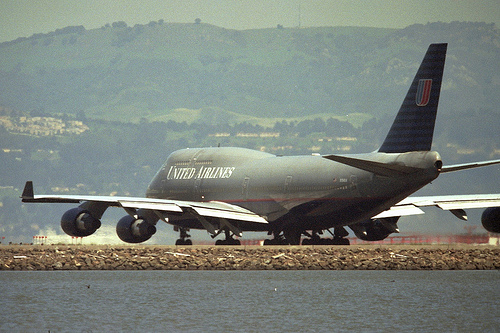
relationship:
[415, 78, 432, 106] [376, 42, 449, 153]
logo on stabilizer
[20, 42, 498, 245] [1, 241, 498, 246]
747 on runway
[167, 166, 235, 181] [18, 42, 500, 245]
sticker written on side of airplane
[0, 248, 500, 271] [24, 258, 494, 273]
rock overlooking rocks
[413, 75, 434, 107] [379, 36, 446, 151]
logo on plane tail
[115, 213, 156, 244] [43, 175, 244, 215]
engine under wings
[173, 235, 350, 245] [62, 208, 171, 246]
wheels of landing gear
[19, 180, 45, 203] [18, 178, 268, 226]
bend tip of wing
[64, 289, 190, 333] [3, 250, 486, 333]
ripples on water surface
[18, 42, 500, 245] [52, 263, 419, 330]
airplane near a body of water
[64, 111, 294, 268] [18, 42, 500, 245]
left wing of airplane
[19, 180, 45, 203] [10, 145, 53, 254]
bend of planes wing bend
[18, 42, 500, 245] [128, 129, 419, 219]
airplane color gray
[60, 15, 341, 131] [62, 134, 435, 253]
mountains behind a plane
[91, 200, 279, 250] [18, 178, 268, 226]
two plane engines below a wing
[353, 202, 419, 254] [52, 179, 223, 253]
engine below a right wing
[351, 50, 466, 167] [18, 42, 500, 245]
vertical stabilizer of airplane